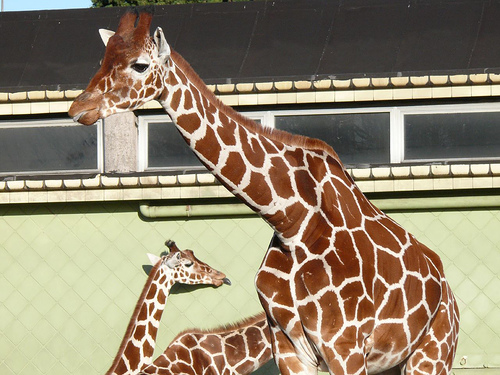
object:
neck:
[175, 70, 292, 230]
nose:
[70, 92, 90, 109]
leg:
[399, 328, 460, 374]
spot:
[225, 149, 247, 181]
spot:
[249, 169, 273, 200]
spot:
[373, 253, 405, 285]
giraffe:
[66, 10, 461, 375]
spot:
[200, 122, 221, 164]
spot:
[400, 272, 425, 312]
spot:
[133, 321, 148, 340]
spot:
[421, 276, 443, 317]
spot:
[329, 282, 367, 320]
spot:
[368, 225, 400, 253]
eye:
[131, 63, 150, 74]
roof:
[0, 1, 500, 100]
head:
[67, 5, 172, 126]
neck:
[120, 284, 169, 370]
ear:
[153, 26, 171, 63]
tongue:
[72, 115, 80, 122]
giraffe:
[104, 238, 231, 375]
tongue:
[223, 278, 232, 285]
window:
[405, 111, 500, 165]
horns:
[117, 7, 153, 33]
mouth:
[68, 107, 99, 125]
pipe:
[136, 200, 259, 219]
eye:
[184, 263, 193, 267]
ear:
[97, 27, 116, 47]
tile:
[6, 216, 103, 309]